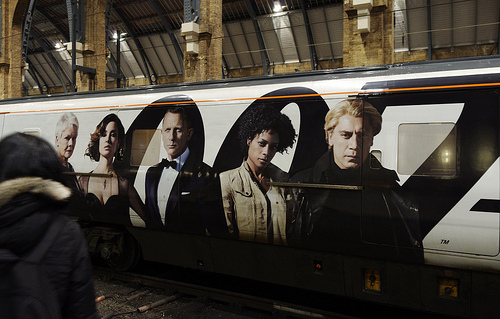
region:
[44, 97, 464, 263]
people on the side of a train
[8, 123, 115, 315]
person outside of the train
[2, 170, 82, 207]
strip of fir around the hood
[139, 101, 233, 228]
James Bond in a suit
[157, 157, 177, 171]
black bowtie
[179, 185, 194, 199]
something white sticking out of the breast pocket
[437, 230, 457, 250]
small black trademark symbol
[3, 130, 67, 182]
jet black hair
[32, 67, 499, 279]
advertisement for a James Bond movie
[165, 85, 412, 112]
thin orange line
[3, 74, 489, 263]
train on the tracks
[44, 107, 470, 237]
movie advertisement on train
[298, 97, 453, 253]
actor on train advertisement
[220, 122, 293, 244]
actor on train advertisement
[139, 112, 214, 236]
actor on train advertisement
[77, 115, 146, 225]
actor on train advertisement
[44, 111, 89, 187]
actor on train advertisement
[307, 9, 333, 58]
window in the building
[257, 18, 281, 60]
window in the building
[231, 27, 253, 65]
window in the building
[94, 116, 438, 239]
Advertisement for a movie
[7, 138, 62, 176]
Person with dark hair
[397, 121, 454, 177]
Window on the train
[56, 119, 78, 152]
A picture of Judy Dench on the train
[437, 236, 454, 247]
Trademark logo on the train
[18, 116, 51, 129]
White paint on the train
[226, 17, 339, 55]
Elevated windows behind the train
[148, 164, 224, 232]
Picture of a man in a tuxedo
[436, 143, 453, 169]
Reflection of light in the window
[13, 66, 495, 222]
White train with an advertisement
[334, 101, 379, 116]
the man has blonde hair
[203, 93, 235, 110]
the stripe is orange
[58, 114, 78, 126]
the woman has gray hair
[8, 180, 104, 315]
the jacket is black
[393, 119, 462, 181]
the train has a window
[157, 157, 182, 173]
the bowtie is black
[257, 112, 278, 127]
the womans hair is black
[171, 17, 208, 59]
the light is off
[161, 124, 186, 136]
the man has eyes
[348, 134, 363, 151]
the man has a nose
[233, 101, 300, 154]
Black, curly hair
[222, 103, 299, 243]
An African American Woman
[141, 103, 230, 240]
A man in a suit and bow tie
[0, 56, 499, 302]
A train coved with a billboard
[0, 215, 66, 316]
A black backpack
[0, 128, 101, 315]
A girl carrying a black backpack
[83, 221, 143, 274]
A wheel on a train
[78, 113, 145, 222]
A woman in a low cut dress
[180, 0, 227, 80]
A brick suppot beam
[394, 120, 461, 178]
A window on a train